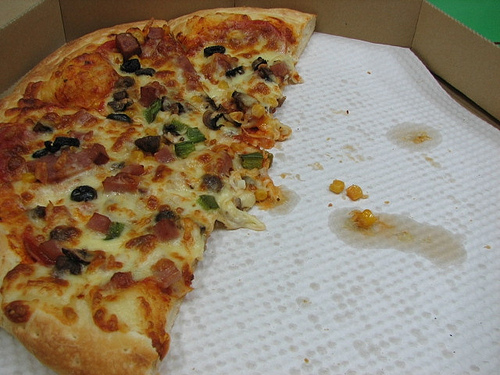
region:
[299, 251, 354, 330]
There is a white layer on this pan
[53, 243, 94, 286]
There is a mushroom on this pizza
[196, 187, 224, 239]
There is a green pepper that is on this pizza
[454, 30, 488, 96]
There is a cardboard container that is here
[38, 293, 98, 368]
There is some brown crust available here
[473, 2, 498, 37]
There is a green color on this pizza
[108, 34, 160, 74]
There are pieces of ham on this pizza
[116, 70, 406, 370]
Jackson Mingus took this photograph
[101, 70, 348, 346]
This city is the city of Chicago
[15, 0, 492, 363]
half eaten pizza in pizza box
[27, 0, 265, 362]
four slices of pizza in pizza box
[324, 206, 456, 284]
grease stain on paper in pizza box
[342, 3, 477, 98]
cardboard pizza box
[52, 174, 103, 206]
black olives on pizza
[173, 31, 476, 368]
white paper lining pizza box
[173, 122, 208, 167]
green peppers on pizza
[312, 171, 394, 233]
yellow pepper slices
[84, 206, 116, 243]
pink ham on pizza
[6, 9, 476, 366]
pizza from a pizza restaurant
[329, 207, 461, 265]
grease stain on the cardboard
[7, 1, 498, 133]
brown cardboard pizza box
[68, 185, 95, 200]
black olive on the pizza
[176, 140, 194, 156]
diced green peppers on the pizza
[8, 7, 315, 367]
pizza is half gone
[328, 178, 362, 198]
kernels of corn from the pizza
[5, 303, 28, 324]
brown bubble on the crust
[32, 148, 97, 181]
piece of meat on the pizza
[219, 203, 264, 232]
cheese falling on the pizza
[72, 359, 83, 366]
hole in the pizza crust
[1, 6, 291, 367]
half eaten pizza right of image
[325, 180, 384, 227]
pieces fallen from pizza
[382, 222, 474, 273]
grease stains of the pizza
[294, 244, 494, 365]
paper packaging under pizza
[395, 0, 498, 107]
cardboard of pizza box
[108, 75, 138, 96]
pizza with olives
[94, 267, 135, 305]
sauce on the pizza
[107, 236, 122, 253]
cheese on the pizza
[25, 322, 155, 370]
brown crust of pizza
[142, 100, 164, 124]
green peppers of pizza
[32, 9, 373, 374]
a pizza in a box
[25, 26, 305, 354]
a half of pizza in a box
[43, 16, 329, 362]
a sliced pizza in a boxx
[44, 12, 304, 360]
five slices of pizza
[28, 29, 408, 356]
five sliced of pizza in a box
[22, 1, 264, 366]
a baked pizza in a box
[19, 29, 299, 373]
a cooked pizza in a box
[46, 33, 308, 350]
a box with a cooked pizz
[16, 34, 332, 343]
a box with a baked pizza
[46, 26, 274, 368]
a pizza with chees